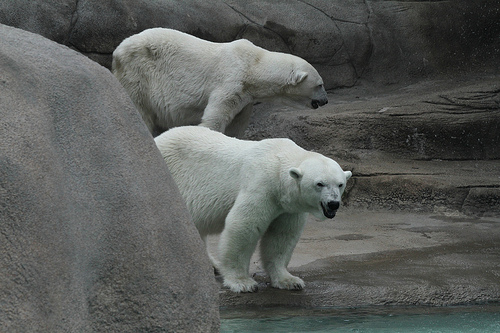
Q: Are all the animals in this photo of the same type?
A: Yes, all the animals are bears.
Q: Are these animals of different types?
A: No, all the animals are bears.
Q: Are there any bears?
A: Yes, there is a bear.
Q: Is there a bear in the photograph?
A: Yes, there is a bear.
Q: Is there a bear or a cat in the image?
A: Yes, there is a bear.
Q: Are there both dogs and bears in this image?
A: No, there is a bear but no dogs.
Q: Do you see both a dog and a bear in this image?
A: No, there is a bear but no dogs.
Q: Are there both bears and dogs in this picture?
A: No, there is a bear but no dogs.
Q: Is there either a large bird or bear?
A: Yes, there is a large bear.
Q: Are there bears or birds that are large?
A: Yes, the bear is large.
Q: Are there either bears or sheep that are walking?
A: Yes, the bear is walking.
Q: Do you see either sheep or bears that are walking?
A: Yes, the bear is walking.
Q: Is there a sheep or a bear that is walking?
A: Yes, the bear is walking.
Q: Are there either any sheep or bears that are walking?
A: Yes, the bear is walking.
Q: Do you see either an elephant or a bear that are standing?
A: Yes, the bear is standing.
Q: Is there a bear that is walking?
A: Yes, there is a bear that is walking.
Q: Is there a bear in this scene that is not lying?
A: Yes, there is a bear that is walking.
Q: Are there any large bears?
A: Yes, there is a large bear.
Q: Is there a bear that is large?
A: Yes, there is a bear that is large.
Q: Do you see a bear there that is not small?
A: Yes, there is a large bear.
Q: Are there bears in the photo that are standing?
A: Yes, there is a bear that is standing.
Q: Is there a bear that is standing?
A: Yes, there is a bear that is standing.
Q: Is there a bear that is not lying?
A: Yes, there is a bear that is standing.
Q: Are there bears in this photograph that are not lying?
A: Yes, there is a bear that is standing.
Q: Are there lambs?
A: No, there are no lambs.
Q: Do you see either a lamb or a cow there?
A: No, there are no lambs or cows.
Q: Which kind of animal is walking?
A: The animal is a bear.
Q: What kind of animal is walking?
A: The animal is a bear.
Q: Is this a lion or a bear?
A: This is a bear.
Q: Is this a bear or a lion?
A: This is a bear.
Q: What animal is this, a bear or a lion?
A: This is a bear.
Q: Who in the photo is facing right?
A: The bear is facing right.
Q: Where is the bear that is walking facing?
A: The bear is facing right.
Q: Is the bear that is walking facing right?
A: Yes, the bear is facing right.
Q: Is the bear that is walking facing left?
A: No, the bear is facing right.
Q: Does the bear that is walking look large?
A: Yes, the bear is large.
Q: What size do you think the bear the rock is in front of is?
A: The bear is large.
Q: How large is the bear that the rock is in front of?
A: The bear is large.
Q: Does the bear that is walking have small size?
A: No, the bear is large.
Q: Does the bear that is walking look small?
A: No, the bear is large.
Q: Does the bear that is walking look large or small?
A: The bear is large.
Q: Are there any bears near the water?
A: Yes, there is a bear near the water.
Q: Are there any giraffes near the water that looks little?
A: No, there is a bear near the water.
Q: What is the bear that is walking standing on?
A: The bear is standing on the rocks.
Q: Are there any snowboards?
A: No, there are no snowboards.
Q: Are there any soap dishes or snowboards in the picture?
A: No, there are no snowboards or soap dishes.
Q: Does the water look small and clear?
A: Yes, the water is small and clear.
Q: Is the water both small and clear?
A: Yes, the water is small and clear.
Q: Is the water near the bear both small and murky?
A: No, the water is small but clear.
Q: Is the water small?
A: Yes, the water is small.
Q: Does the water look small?
A: Yes, the water is small.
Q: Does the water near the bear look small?
A: Yes, the water is small.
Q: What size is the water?
A: The water is small.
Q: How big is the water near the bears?
A: The water is small.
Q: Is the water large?
A: No, the water is small.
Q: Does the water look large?
A: No, the water is small.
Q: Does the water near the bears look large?
A: No, the water is small.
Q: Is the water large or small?
A: The water is small.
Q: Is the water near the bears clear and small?
A: Yes, the water is clear and small.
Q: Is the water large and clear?
A: No, the water is clear but small.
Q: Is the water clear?
A: Yes, the water is clear.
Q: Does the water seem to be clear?
A: Yes, the water is clear.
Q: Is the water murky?
A: No, the water is clear.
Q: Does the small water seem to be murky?
A: No, the water is clear.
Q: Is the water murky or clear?
A: The water is clear.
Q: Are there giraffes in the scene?
A: No, there are no giraffes.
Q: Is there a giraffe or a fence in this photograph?
A: No, there are no giraffes or fences.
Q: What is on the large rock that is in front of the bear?
A: The spots are on the rock.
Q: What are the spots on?
A: The spots are on the rock.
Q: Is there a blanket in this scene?
A: No, there are no blankets.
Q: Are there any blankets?
A: No, there are no blankets.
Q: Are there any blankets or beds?
A: No, there are no blankets or beds.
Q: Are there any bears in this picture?
A: Yes, there are bears.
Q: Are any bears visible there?
A: Yes, there are bears.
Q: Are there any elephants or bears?
A: Yes, there are bears.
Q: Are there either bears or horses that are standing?
A: Yes, the bears are standing.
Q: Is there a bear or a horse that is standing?
A: Yes, the bears are standing.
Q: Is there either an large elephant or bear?
A: Yes, there are large bears.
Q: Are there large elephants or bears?
A: Yes, there are large bears.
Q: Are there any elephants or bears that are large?
A: Yes, the bears are large.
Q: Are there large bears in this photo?
A: Yes, there are large bears.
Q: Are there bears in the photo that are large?
A: Yes, there are bears that are large.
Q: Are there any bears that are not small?
A: Yes, there are large bears.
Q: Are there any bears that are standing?
A: Yes, there are bears that are standing.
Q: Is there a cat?
A: No, there are no cats.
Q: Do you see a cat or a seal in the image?
A: No, there are no cats or seals.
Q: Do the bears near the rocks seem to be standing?
A: Yes, the bears are standing.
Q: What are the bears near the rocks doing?
A: The bears are standing.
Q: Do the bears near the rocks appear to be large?
A: Yes, the bears are large.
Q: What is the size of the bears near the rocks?
A: The bears are large.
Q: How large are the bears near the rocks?
A: The bears are large.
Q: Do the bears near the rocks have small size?
A: No, the bears are large.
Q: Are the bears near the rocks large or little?
A: The bears are large.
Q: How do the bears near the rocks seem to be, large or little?
A: The bears are large.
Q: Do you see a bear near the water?
A: Yes, there are bears near the water.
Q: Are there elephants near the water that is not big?
A: No, there are bears near the water.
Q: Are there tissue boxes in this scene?
A: No, there are no tissue boxes.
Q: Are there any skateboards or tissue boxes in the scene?
A: No, there are no tissue boxes or skateboards.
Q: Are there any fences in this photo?
A: No, there are no fences.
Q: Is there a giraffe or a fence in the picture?
A: No, there are no fences or giraffes.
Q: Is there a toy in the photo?
A: No, there are no toys.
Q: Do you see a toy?
A: No, there are no toys.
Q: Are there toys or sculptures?
A: No, there are no toys or sculptures.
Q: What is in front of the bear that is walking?
A: The rock is in front of the bear.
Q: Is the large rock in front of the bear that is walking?
A: Yes, the rock is in front of the bear.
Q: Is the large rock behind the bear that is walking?
A: No, the rock is in front of the bear.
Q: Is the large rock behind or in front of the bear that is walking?
A: The rock is in front of the bear.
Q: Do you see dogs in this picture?
A: No, there are no dogs.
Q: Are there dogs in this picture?
A: No, there are no dogs.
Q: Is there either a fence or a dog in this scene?
A: No, there are no dogs or fences.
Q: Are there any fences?
A: No, there are no fences.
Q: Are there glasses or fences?
A: No, there are no fences or glasses.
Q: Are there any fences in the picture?
A: No, there are no fences.